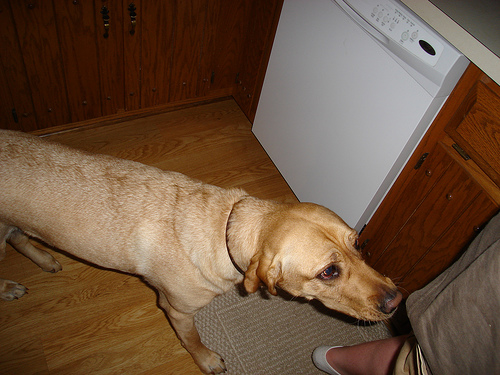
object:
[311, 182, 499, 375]
person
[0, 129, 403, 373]
dog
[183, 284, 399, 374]
rug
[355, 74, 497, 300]
kitchen cupboard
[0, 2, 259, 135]
door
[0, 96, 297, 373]
floor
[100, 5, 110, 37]
handle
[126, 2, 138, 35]
handle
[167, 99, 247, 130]
ground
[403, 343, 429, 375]
socks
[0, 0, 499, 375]
kitchen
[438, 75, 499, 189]
drawer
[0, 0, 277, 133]
cabinets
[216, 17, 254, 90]
wood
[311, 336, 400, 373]
shoes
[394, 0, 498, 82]
kitchen counter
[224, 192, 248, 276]
collar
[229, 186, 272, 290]
dog's neck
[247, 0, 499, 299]
dishwasher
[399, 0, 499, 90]
countertop